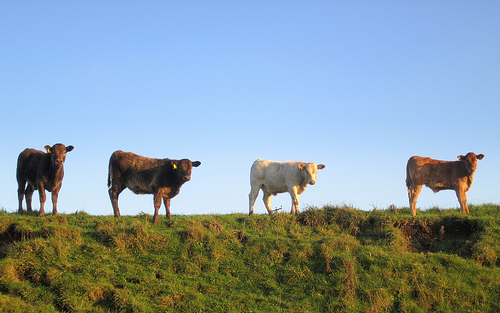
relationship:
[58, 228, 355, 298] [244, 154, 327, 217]
grass under cows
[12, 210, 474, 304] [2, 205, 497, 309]
hill with grass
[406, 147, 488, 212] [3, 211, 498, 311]
cow standing on hill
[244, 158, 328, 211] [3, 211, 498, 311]
cow standing on hill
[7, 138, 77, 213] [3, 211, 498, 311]
cow standing on hill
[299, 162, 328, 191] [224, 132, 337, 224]
face of cow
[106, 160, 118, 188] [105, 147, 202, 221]
tail of cow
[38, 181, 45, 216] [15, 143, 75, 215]
leg on cow